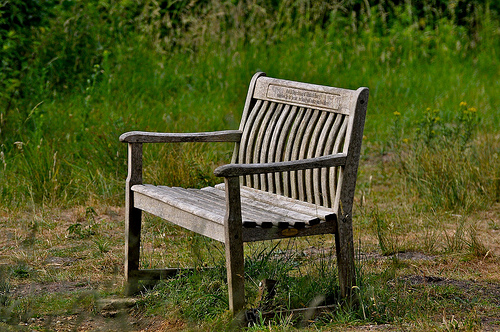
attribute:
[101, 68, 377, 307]
bench — wooden, beaten, brown, large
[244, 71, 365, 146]
back — wood, curved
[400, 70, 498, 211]
grass — tall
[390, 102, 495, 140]
flowers — yellow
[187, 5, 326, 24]
tips — brown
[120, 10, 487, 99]
grass — tall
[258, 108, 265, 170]
slats — vertical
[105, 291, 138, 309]
stone — large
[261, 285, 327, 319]
stump — wood, large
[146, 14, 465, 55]
trees — green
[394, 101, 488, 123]
dandelions — yellow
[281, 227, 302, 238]
oval — gold